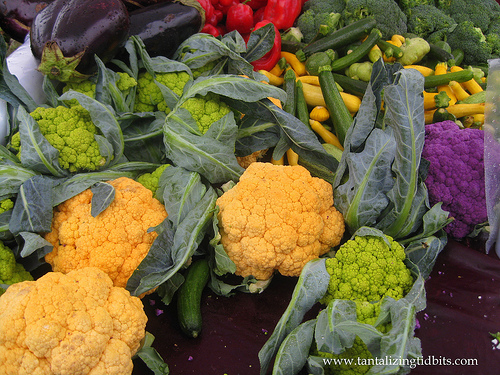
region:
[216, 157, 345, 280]
Stalk of yellow cauliflower.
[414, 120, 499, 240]
A stalk of purple cauliflower.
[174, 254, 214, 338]
A green colored cucumber.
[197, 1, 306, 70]
A pile of red peppers.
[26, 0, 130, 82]
A large purple eggplant.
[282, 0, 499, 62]
A pile of broccoli.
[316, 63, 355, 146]
A green colored zucchini.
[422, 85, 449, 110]
A yellow colored squash.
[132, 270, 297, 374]
A brown colored table.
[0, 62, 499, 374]
A pile of cauliflower.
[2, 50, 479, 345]
vegetables in the garden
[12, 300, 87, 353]
the cauliflower is yellow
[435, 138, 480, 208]
the flowers are purple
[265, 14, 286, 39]
the peppers are red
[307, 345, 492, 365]
logo on the right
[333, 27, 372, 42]
the cucumber is green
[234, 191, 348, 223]
head of the cauliflower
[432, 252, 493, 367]
a table under the vegetables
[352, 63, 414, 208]
a leaf of kale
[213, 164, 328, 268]
cauliflower on the table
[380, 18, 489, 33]
broccoli on the table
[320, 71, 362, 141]
a green zucchini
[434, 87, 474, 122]
yellow squash on the table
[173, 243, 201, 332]
a cucumber on the table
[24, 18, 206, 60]
an eggplant on the table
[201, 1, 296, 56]
red peppers on the table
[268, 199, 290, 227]
the califlower is light orange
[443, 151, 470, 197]
the califlower is purple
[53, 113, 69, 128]
the califlower is light green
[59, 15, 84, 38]
the eggplant is purple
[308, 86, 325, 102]
the squash is yellow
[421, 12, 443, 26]
the broccoli is dark green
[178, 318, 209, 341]
the zuccini is on the table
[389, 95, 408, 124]
the leaf has vines in it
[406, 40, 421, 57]
the tomato is pale green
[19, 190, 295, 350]
yellow cauliflower on dirt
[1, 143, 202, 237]
green leaves on cauliflower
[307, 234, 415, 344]
dark green cauliflower in leaves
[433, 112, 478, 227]
purple cauliflower in leaves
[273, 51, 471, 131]
yellow squash in rear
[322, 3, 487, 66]
green broccoli in rear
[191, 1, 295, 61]
red pepper in back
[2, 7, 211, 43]
large eggplant near peppers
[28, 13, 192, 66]
eggplant is dark purple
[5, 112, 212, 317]
leaves are dark green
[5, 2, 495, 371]
An array of vegetables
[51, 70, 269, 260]
An array of vegetables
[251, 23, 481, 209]
An array of vegetables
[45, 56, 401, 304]
An array of vegetables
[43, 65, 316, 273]
An array of vegetables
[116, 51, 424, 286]
An array of vegetables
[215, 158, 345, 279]
the cauliflower is yellow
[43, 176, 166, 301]
the cauliflower is yellow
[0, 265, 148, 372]
the cauliflower is yellow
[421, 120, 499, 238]
the cauliflower is purple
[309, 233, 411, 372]
the cauliflower is green